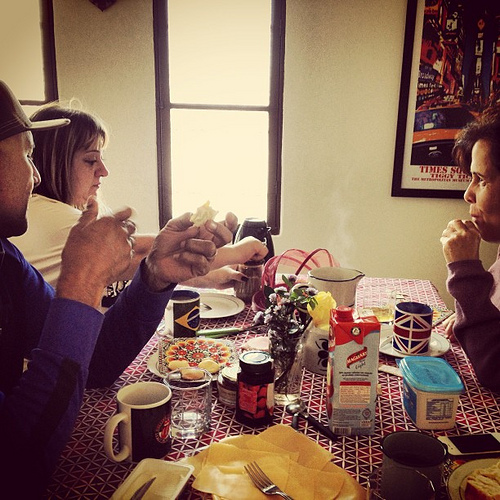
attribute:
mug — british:
[378, 290, 441, 355]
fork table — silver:
[238, 453, 295, 498]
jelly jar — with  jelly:
[238, 345, 280, 422]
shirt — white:
[15, 191, 91, 296]